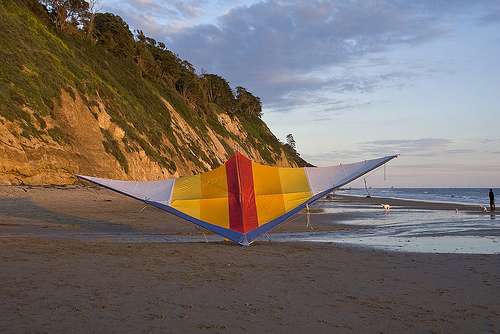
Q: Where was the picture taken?
A: It was taken at the beach.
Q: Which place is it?
A: It is a beach.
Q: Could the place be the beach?
A: Yes, it is the beach.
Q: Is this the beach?
A: Yes, it is the beach.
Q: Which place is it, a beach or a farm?
A: It is a beach.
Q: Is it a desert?
A: No, it is a beach.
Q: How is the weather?
A: It is clear.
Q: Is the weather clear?
A: Yes, it is clear.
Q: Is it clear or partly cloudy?
A: It is clear.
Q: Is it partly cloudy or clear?
A: It is clear.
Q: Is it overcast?
A: No, it is clear.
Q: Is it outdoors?
A: Yes, it is outdoors.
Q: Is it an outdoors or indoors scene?
A: It is outdoors.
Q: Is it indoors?
A: No, it is outdoors.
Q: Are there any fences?
A: No, there are no fences.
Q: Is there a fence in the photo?
A: No, there are no fences.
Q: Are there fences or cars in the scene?
A: No, there are no fences or cars.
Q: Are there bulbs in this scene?
A: No, there are no bulbs.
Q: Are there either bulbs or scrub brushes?
A: No, there are no bulbs or scrub brushes.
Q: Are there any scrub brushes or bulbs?
A: No, there are no bulbs or scrub brushes.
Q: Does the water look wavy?
A: Yes, the water is wavy.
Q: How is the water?
A: The water is wavy.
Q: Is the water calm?
A: No, the water is wavy.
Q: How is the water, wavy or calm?
A: The water is wavy.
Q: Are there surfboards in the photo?
A: No, there are no surfboards.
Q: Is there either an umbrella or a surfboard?
A: No, there are no surfboards or umbrellas.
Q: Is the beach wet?
A: Yes, the beach is wet.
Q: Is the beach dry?
A: No, the beach is wet.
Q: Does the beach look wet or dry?
A: The beach is wet.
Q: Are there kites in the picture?
A: Yes, there is a kite.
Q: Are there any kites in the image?
A: Yes, there is a kite.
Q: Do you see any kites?
A: Yes, there is a kite.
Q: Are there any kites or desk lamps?
A: Yes, there is a kite.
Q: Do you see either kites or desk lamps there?
A: Yes, there is a kite.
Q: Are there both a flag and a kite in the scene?
A: No, there is a kite but no flags.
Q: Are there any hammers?
A: No, there are no hammers.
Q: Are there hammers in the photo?
A: No, there are no hammers.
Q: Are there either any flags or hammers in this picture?
A: No, there are no hammers or flags.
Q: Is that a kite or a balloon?
A: That is a kite.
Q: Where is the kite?
A: The kite is on the beach.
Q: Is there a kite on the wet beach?
A: Yes, there is a kite on the beach.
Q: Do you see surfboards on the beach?
A: No, there is a kite on the beach.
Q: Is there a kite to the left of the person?
A: Yes, there is a kite to the left of the person.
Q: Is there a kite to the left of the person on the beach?
A: Yes, there is a kite to the left of the person.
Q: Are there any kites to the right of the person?
A: No, the kite is to the left of the person.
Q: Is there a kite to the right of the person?
A: No, the kite is to the left of the person.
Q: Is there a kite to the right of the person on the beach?
A: No, the kite is to the left of the person.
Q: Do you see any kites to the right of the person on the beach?
A: No, the kite is to the left of the person.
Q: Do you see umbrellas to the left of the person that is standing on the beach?
A: No, there is a kite to the left of the person.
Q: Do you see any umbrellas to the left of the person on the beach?
A: No, there is a kite to the left of the person.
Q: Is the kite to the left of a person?
A: Yes, the kite is to the left of a person.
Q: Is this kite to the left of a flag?
A: No, the kite is to the left of a person.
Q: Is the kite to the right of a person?
A: No, the kite is to the left of a person.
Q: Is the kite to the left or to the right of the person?
A: The kite is to the left of the person.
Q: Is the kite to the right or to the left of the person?
A: The kite is to the left of the person.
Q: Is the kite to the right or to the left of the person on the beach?
A: The kite is to the left of the person.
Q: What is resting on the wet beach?
A: The kite is resting on the beach.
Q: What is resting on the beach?
A: The kite is resting on the beach.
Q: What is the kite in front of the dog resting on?
A: The kite is resting on the beach.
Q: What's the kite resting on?
A: The kite is resting on the beach.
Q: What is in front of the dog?
A: The kite is in front of the dog.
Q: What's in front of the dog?
A: The kite is in front of the dog.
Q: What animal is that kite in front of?
A: The kite is in front of the dog.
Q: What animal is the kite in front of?
A: The kite is in front of the dog.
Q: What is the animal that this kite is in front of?
A: The animal is a dog.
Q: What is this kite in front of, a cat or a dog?
A: The kite is in front of a dog.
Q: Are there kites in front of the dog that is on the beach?
A: Yes, there is a kite in front of the dog.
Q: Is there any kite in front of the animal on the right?
A: Yes, there is a kite in front of the dog.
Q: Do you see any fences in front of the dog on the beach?
A: No, there is a kite in front of the dog.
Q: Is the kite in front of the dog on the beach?
A: Yes, the kite is in front of the dog.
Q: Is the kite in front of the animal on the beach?
A: Yes, the kite is in front of the dog.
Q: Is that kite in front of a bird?
A: No, the kite is in front of the dog.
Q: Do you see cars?
A: No, there are no cars.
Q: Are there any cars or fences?
A: No, there are no cars or fences.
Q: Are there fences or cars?
A: No, there are no cars or fences.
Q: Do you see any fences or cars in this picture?
A: No, there are no cars or fences.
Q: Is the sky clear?
A: Yes, the sky is clear.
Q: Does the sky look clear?
A: Yes, the sky is clear.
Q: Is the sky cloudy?
A: No, the sky is clear.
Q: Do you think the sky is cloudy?
A: No, the sky is clear.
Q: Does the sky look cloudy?
A: No, the sky is clear.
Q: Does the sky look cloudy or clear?
A: The sky is clear.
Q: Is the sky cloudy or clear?
A: The sky is clear.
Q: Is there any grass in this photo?
A: Yes, there is grass.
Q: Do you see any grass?
A: Yes, there is grass.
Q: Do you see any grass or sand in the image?
A: Yes, there is grass.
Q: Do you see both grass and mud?
A: No, there is grass but no mud.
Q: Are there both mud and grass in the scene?
A: No, there is grass but no mud.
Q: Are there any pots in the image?
A: No, there are no pots.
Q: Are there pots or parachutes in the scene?
A: No, there are no pots or parachutes.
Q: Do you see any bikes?
A: No, there are no bikes.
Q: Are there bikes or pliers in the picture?
A: No, there are no bikes or pliers.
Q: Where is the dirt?
A: The dirt is on the hill.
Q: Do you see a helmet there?
A: No, there are no helmets.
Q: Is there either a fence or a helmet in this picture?
A: No, there are no helmets or fences.